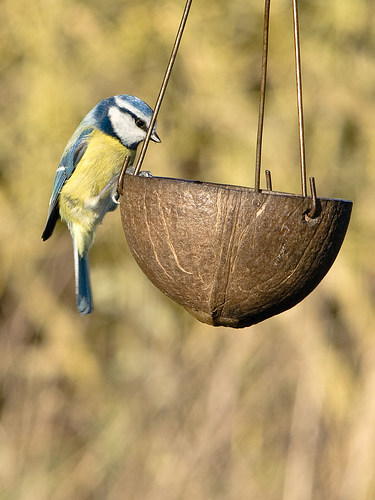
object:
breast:
[83, 140, 121, 210]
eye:
[136, 118, 146, 128]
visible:
[146, 37, 311, 147]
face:
[122, 97, 157, 145]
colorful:
[43, 87, 157, 266]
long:
[62, 247, 102, 319]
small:
[129, 116, 150, 129]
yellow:
[66, 135, 128, 220]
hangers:
[159, 101, 305, 122]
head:
[93, 96, 177, 147]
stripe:
[117, 108, 154, 135]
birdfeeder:
[146, 234, 297, 298]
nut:
[177, 264, 244, 307]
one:
[52, 138, 70, 212]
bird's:
[111, 165, 153, 206]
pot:
[113, 163, 352, 322]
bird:
[39, 88, 161, 313]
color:
[77, 137, 119, 238]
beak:
[146, 122, 167, 150]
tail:
[70, 249, 91, 328]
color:
[74, 255, 95, 321]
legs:
[112, 166, 149, 206]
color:
[103, 156, 146, 245]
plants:
[35, 326, 161, 469]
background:
[10, 309, 363, 500]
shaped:
[120, 183, 350, 329]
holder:
[299, 184, 318, 224]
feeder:
[115, 231, 306, 361]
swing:
[141, 74, 338, 211]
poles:
[292, 0, 325, 190]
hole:
[292, 176, 317, 238]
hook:
[115, 153, 129, 196]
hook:
[291, 174, 324, 225]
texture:
[170, 244, 251, 293]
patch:
[197, 185, 255, 319]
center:
[163, 166, 291, 340]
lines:
[168, 205, 310, 271]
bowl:
[120, 160, 354, 332]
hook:
[264, 171, 277, 184]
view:
[221, 159, 324, 264]